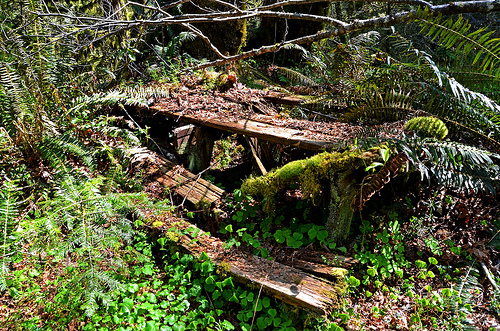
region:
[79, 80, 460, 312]
wooden boards on a jungle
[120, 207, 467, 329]
light green lucky clovers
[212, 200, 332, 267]
lucky clovers between wooden boards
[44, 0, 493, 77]
dry branch of a fallen tree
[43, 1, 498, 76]
dry brown branch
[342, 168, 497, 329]
ground under trees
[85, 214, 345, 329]
a bunch of lucky clovers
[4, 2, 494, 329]
jungle full of trees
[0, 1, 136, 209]
green light bushes in the left side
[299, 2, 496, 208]
dark green bushes in the right side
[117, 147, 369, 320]
broken wooden picnic table bench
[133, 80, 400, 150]
broken wooden picnic table top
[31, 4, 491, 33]
tree branch with no leaves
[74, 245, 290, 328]
green ivy on ground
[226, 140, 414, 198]
green moss on wood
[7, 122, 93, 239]
green fern on ground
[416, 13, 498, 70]
green palm leaf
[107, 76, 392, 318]
old picnic table on ground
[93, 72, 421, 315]
broken up picnic table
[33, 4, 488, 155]
branches on broken table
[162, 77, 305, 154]
wooden brown bench in woods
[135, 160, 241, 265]
wooden brown bench in woods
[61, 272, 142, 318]
green leaves on brown branches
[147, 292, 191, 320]
green leaves on brown branches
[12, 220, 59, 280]
green leaves on brown branches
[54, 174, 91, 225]
green leaves on brown branches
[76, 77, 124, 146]
green leaves on brown branches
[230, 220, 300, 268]
green leaves on brown branches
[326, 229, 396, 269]
green leaves on brown branches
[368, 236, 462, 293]
green leaves on brown branches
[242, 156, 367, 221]
Green moss growing on a log.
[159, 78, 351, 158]
Brown logs in the sun.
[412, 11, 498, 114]
Green ferns growing uncontroably.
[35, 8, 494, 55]
Dried dead branches of a fallen tree.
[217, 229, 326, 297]
Shadows bouncing off a log in the sun.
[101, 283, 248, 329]
Vines running and growing along the ground.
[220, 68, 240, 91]
Orange flower among logs and weeds.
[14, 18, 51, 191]
Brownish dying fern on left side.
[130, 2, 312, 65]
Cave entrance located in a forest.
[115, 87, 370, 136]
Bridge made of fallen logs.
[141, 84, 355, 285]
Plank is brown color.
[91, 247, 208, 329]
Leaves are green color.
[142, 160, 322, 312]
Two planks are down below.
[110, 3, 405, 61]
Woods are brown color.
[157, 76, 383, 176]
Planks are of wood.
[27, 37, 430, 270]
place is dirty.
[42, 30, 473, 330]
Shadow falls on ground.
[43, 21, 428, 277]
Day time picture.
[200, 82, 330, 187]
Planks are made of wood.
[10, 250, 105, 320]
Dried leaves are on ground.